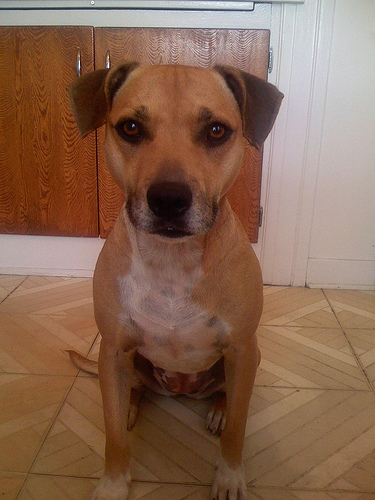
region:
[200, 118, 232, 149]
eye of a brown dog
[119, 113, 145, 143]
eye of a brown dog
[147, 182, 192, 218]
black nose of a dog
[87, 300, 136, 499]
leg of a dog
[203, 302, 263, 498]
leg of a dog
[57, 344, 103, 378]
tail of a dog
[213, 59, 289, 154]
ear of a brown dog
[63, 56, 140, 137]
ear of a brown dog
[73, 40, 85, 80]
silver handle on the cabinet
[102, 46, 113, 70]
silver handle on the cabinet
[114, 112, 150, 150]
Right eye of dog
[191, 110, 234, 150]
Left eye of dog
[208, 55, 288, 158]
Left ear of dog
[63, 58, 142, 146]
Right ear of dog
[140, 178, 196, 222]
Nose of brown dog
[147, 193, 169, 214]
Right nostril of dog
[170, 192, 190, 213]
Left nostril of dog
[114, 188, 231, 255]
Mouth of brown dog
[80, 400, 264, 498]
Paws of brown dog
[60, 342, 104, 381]
Tail of brown dog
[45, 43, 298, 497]
A brown and white dog with brown eyes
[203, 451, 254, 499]
A dog's white paw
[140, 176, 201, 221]
A dog's black nose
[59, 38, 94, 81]
A silver cupboard handle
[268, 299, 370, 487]
A tile floor surface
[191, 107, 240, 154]
A dog's brown eye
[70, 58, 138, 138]
A dog's right ear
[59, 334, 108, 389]
A dog's brown tail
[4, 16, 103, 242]
A brown wooden cupboard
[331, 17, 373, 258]
A white wall surface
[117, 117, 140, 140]
eye of a dog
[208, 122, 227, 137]
eye of a dog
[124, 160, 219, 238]
a dog's snout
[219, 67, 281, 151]
a dog's left ear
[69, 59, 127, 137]
a dog's right ear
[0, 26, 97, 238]
wooden cabinet door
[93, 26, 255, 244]
a wooden cabinet door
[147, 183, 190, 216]
a dog's nose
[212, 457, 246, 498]
white paw of a dog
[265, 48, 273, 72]
a metal hinge on a cabinet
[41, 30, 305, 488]
the dog is sitting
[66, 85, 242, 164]
the eyes are open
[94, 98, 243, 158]
the eyes are brown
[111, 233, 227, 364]
the chest is white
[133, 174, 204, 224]
the nose is black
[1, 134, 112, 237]
the doors are brown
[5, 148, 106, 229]
the doors are made of wood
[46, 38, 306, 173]
the ears are down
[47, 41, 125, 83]
the handles are silver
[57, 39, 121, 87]
the handles are made of metal